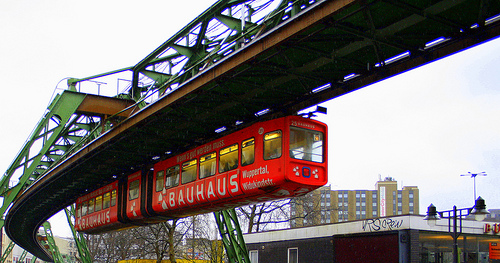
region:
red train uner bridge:
[135, 136, 330, 193]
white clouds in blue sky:
[384, 105, 419, 135]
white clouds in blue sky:
[440, 86, 498, 144]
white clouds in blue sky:
[338, 113, 375, 164]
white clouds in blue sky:
[361, 96, 472, 138]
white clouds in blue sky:
[412, 71, 470, 136]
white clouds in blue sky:
[382, 86, 443, 136]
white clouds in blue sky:
[40, 21, 100, 51]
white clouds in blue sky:
[410, 109, 498, 169]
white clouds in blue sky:
[344, 118, 416, 155]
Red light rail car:
[72, 99, 331, 236]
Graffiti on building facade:
[360, 213, 403, 232]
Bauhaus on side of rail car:
[161, 169, 246, 209]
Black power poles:
[425, 199, 494, 258]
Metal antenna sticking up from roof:
[458, 162, 488, 222]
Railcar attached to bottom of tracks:
[56, 38, 349, 250]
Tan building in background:
[293, 175, 422, 224]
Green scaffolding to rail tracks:
[0, 70, 106, 190]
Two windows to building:
[245, 246, 302, 261]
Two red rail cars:
[68, 103, 335, 233]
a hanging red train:
[65, 113, 326, 230]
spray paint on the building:
[361, 216, 405, 233]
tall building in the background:
[289, 175, 417, 227]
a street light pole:
[462, 167, 484, 204]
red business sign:
[480, 219, 498, 234]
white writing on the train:
[161, 166, 273, 202]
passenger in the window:
[218, 144, 238, 174]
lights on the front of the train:
[292, 165, 320, 180]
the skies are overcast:
[3, 0, 490, 192]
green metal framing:
[0, 0, 251, 214]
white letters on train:
[167, 191, 194, 208]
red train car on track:
[66, 193, 129, 228]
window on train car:
[215, 149, 236, 172]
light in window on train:
[221, 150, 239, 157]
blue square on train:
[300, 163, 313, 178]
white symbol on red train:
[155, 192, 167, 212]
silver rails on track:
[134, 97, 149, 111]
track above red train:
[152, 121, 212, 148]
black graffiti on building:
[361, 217, 405, 229]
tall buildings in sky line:
[328, 186, 422, 220]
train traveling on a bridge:
[55, 97, 347, 241]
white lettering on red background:
[168, 174, 241, 211]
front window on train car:
[288, 128, 324, 163]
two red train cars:
[57, 118, 333, 248]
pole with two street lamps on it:
[428, 190, 488, 262]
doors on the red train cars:
[116, 171, 156, 225]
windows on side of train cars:
[74, 124, 277, 221]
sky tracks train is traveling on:
[10, 0, 466, 250]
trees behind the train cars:
[70, 114, 311, 261]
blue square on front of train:
[299, 163, 315, 179]